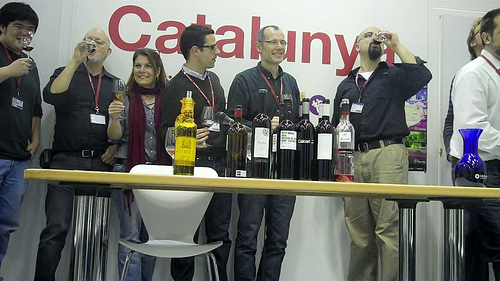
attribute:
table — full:
[20, 164, 499, 279]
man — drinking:
[323, 18, 435, 278]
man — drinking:
[331, 25, 432, 280]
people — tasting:
[8, 15, 499, 225]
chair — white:
[47, 177, 241, 279]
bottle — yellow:
[163, 85, 201, 187]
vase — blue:
[450, 127, 485, 185]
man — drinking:
[59, 31, 154, 142]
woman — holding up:
[98, 31, 200, 233]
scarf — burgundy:
[123, 87, 170, 174]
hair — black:
[179, 19, 213, 62]